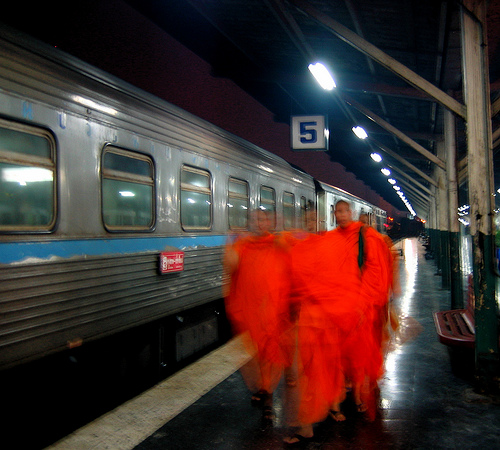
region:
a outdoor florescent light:
[300, 52, 347, 117]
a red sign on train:
[140, 250, 195, 280]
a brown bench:
[425, 281, 485, 371]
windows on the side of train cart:
[0, 115, 160, 240]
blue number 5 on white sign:
[282, 101, 338, 158]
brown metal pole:
[460, 20, 494, 265]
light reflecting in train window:
[109, 181, 151, 216]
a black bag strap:
[353, 218, 371, 284]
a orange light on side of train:
[64, 333, 83, 352]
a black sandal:
[259, 429, 326, 448]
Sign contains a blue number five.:
[282, 104, 339, 155]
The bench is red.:
[428, 293, 480, 345]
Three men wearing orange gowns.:
[217, 204, 390, 441]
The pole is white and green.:
[430, 149, 470, 313]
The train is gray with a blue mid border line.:
[57, 182, 119, 334]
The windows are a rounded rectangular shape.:
[89, 138, 167, 239]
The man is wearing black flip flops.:
[275, 397, 323, 446]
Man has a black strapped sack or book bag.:
[327, 212, 386, 293]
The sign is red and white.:
[155, 247, 192, 279]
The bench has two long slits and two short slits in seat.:
[432, 309, 482, 348]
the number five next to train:
[277, 97, 347, 174]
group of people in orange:
[186, 179, 407, 348]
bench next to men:
[422, 291, 474, 363]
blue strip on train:
[53, 219, 127, 291]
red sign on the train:
[145, 236, 197, 293]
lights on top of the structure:
[311, 49, 422, 201]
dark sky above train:
[121, 47, 185, 93]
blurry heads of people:
[229, 207, 324, 254]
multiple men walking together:
[198, 186, 412, 319]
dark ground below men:
[400, 360, 455, 427]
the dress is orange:
[215, 159, 414, 427]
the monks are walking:
[206, 182, 415, 448]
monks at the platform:
[217, 143, 407, 448]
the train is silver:
[28, 51, 209, 349]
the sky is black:
[93, 12, 240, 87]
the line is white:
[98, 356, 206, 441]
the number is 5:
[272, 89, 349, 160]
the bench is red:
[413, 259, 498, 390]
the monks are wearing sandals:
[235, 370, 393, 435]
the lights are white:
[283, 40, 458, 252]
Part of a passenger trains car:
[2, 38, 215, 363]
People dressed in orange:
[215, 200, 400, 440]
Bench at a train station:
[430, 265, 482, 365]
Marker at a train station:
[282, 107, 339, 152]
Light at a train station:
[305, 55, 365, 107]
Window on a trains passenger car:
[90, 140, 166, 235]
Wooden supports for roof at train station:
[328, 20, 496, 155]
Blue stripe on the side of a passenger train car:
[2, 239, 139, 265]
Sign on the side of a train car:
[153, 251, 193, 276]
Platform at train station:
[397, 375, 482, 435]